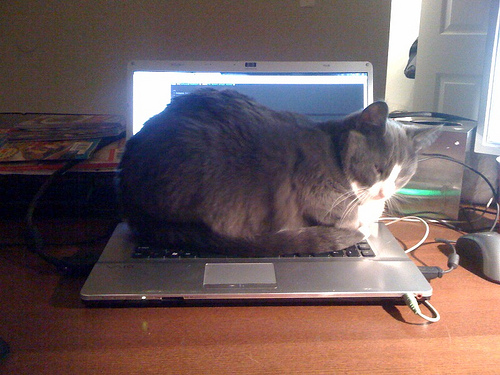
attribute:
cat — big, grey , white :
[114, 88, 431, 252]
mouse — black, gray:
[456, 223, 484, 268]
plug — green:
[402, 292, 442, 321]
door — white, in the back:
[416, 2, 484, 152]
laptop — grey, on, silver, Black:
[65, 52, 430, 309]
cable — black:
[23, 145, 106, 271]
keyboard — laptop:
[120, 217, 375, 264]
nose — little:
[370, 183, 390, 203]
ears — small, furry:
[347, 91, 454, 151]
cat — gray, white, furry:
[117, 77, 451, 254]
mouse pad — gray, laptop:
[195, 256, 282, 290]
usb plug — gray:
[415, 259, 445, 283]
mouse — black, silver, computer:
[452, 225, 483, 273]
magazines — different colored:
[0, 111, 126, 177]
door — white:
[419, 4, 484, 115]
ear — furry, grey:
[347, 100, 390, 117]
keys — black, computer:
[135, 220, 289, 267]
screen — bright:
[124, 65, 383, 138]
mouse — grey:
[448, 231, 498, 277]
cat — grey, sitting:
[115, 84, 439, 239]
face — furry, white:
[316, 120, 419, 209]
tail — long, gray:
[124, 210, 226, 274]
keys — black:
[144, 230, 251, 254]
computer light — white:
[115, 74, 333, 154]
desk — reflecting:
[91, 306, 193, 352]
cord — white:
[405, 305, 456, 345]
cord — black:
[31, 230, 140, 306]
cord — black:
[399, 246, 472, 286]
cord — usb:
[406, 234, 436, 277]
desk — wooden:
[188, 332, 280, 368]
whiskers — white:
[345, 192, 363, 224]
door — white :
[415, 2, 495, 142]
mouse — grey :
[458, 230, 495, 279]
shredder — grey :
[383, 109, 471, 229]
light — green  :
[401, 186, 458, 195]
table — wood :
[7, 174, 492, 373]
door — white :
[410, 3, 490, 145]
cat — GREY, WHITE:
[135, 104, 421, 258]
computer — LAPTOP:
[79, 51, 409, 312]